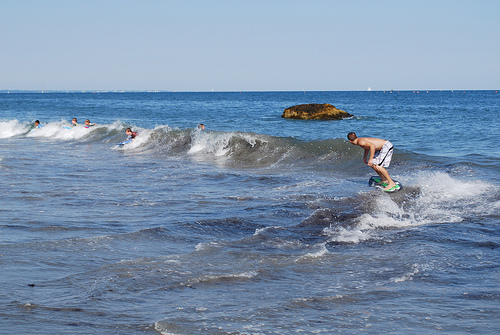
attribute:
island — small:
[282, 103, 352, 122]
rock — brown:
[284, 100, 356, 118]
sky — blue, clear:
[23, 9, 478, 90]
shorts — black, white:
[367, 140, 392, 177]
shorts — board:
[367, 140, 396, 172]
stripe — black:
[372, 141, 401, 172]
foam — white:
[370, 191, 400, 220]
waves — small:
[17, 106, 424, 186]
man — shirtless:
[344, 129, 399, 196]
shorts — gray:
[369, 134, 395, 172]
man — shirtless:
[347, 128, 405, 193]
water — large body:
[87, 183, 209, 261]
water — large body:
[289, 255, 407, 330]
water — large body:
[28, 160, 151, 220]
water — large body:
[358, 252, 471, 326]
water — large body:
[339, 276, 425, 325]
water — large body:
[334, 241, 458, 306]